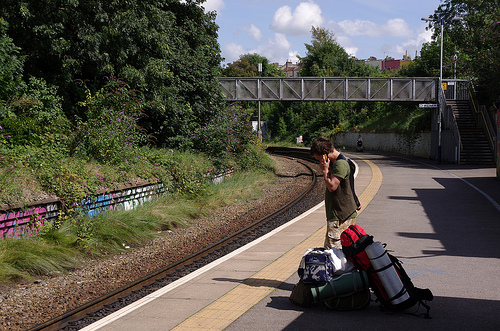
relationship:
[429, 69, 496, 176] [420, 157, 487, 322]
stairs to walkway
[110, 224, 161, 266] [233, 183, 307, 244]
rock near track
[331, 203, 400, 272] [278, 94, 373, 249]
luggage next to man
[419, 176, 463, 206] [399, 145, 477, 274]
shadow on pavement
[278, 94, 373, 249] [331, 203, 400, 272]
man has luggage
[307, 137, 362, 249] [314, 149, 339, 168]
man on phone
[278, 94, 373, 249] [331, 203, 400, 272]
man and luggage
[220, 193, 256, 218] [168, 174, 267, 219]
gravel on side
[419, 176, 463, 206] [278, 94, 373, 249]
shadow of man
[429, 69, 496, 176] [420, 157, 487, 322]
stairs leading walkway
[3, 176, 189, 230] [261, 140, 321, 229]
wall along tracks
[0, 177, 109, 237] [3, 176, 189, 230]
graffiti on wall